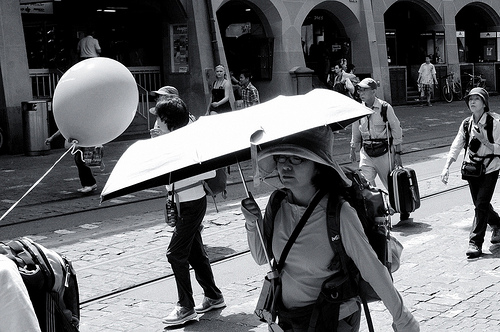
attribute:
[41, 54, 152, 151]
balloon — white, medium, big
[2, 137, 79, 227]
string — white, long, thin, swirly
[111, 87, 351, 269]
umbrella — flat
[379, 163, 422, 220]
suitcase — plastic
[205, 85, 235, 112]
dress — short, black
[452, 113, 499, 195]
shirt — white, sleeved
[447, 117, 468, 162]
sleeves — long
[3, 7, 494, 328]
picture — grey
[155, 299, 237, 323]
sneakers — flat